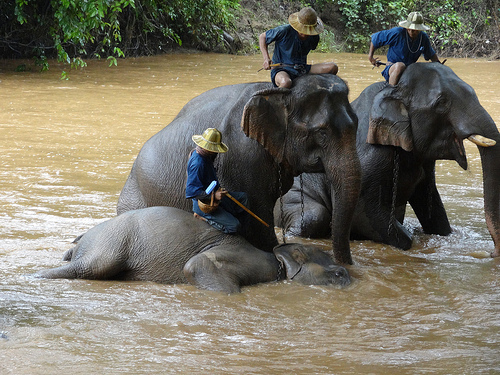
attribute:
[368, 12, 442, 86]
person — present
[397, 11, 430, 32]
hat — weaved, straw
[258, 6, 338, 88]
person — present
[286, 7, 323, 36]
hat — weaved, straw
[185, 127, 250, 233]
person — present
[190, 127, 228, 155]
hat — weaved, straw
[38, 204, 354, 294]
elephant — fallen, laying, grey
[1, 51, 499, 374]
water — dirty, brown, turbid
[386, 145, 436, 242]
chains — metal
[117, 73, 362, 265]
elephant — grey, brown, dark grey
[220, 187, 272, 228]
stick — long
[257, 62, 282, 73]
stick — short, wooden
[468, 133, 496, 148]
tusk — white, large, fat, tan colored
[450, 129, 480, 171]
mouth — open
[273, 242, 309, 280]
ear — big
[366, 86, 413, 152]
ear — big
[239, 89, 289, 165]
ear — big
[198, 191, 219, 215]
basket — small, wooden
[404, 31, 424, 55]
necklace — light grey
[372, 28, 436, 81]
outfit — blue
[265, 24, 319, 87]
outfit — blue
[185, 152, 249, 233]
outfit — blue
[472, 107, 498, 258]
trunk — long, large, brown, dark grey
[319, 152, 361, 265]
trunk — long, large, brown, dark grey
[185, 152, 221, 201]
shirt — long sleeve, blue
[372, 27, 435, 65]
shirt — blue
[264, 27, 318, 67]
shirt — blue, dark blue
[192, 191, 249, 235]
jeans — blue